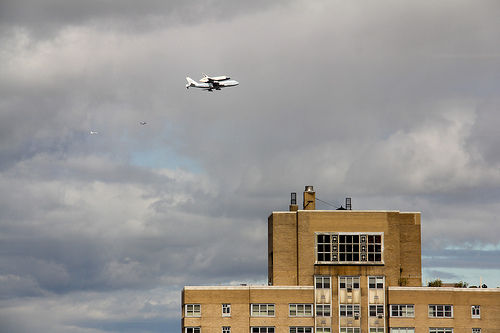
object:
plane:
[185, 73, 238, 92]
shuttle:
[199, 74, 230, 83]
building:
[181, 185, 500, 332]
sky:
[1, 0, 498, 332]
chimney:
[304, 185, 315, 209]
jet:
[139, 120, 148, 126]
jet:
[90, 130, 99, 136]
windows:
[185, 232, 481, 333]